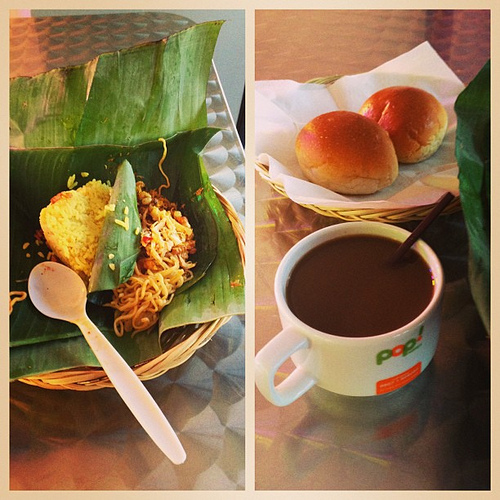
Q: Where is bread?
A: In a basket.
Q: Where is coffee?
A: In a cup.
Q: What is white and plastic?
A: Spoon.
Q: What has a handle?
A: The cup.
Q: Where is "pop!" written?
A: On side of the cup.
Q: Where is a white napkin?
A: In basket.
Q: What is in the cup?
A: A stirrer.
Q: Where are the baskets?
A: On a table.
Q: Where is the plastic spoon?
A: In the bowl.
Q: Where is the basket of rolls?
A: On the table.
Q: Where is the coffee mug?
A: Near the rolls.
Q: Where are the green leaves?
A: Underneath the salad.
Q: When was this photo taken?
A: During a meal.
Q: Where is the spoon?
A: On the plate with green leaves.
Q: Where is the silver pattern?
A: On top of the table.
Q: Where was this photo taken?
A: At a restaurant.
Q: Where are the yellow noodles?
A: On the green leaves.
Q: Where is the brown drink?
A: In the white mug.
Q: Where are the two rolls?
A: On the white napkin in the basket.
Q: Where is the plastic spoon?
A: In the left basket.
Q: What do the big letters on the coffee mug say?
A: Pop.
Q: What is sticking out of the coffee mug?
A: Black stirrer.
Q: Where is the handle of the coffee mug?
A: Lower left side.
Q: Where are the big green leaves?
A: In the left basket.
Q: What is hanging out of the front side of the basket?
A: Handle of plastic spoon.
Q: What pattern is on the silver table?
A: Diamond-like swirls.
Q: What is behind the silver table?
A: White wall.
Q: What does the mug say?
A: Pop.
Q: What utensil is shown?
A: A spoon.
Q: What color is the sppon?
A: White.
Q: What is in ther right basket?
A: Bread.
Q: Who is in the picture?
A: No one.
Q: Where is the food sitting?
A: In baskets.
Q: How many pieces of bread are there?
A: 2.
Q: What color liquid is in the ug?
A: Brown.